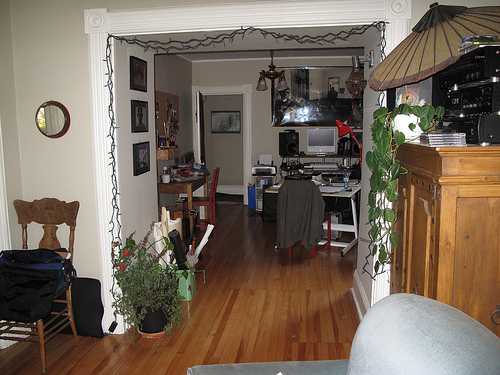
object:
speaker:
[278, 131, 300, 156]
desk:
[262, 150, 362, 257]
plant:
[110, 220, 195, 348]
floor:
[0, 194, 357, 373]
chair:
[2, 197, 79, 374]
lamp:
[335, 119, 357, 142]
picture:
[211, 112, 240, 131]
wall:
[200, 95, 244, 186]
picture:
[133, 61, 146, 89]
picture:
[130, 100, 149, 132]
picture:
[137, 148, 148, 170]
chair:
[276, 178, 331, 259]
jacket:
[274, 180, 323, 249]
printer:
[251, 156, 277, 176]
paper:
[258, 154, 272, 166]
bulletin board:
[155, 90, 179, 153]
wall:
[154, 54, 192, 235]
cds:
[419, 143, 467, 147]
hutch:
[388, 139, 499, 339]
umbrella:
[369, 2, 499, 92]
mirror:
[36, 100, 71, 139]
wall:
[0, 1, 99, 301]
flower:
[118, 262, 125, 271]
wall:
[112, 37, 158, 332]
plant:
[362, 104, 443, 279]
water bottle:
[342, 170, 350, 189]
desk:
[265, 180, 361, 258]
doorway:
[190, 85, 253, 219]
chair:
[181, 168, 220, 233]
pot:
[132, 301, 170, 333]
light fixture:
[256, 51, 288, 92]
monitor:
[305, 129, 338, 154]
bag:
[0, 248, 75, 323]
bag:
[38, 277, 103, 337]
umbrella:
[183, 210, 198, 258]